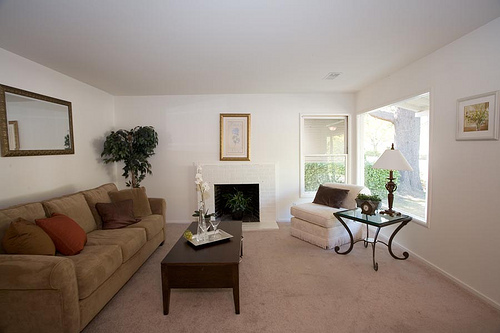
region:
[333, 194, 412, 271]
a glass and wrought iron end table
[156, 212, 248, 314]
a wooden rectangular coffee table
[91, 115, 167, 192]
a fake house tree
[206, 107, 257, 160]
a picture in a gold frame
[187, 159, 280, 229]
a white fire place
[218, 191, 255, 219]
a plant inside the fireplace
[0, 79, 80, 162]
a large bronze mirror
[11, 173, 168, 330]
a soft brown sofa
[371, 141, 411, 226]
an ornate lamp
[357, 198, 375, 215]
a small clock on the table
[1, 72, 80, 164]
Mirror hanging on the wall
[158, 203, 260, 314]
Brown coffee table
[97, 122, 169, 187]
Tall green plant in corner of room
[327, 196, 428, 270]
Glass top table with metal frame and legs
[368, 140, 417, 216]
Table lamp with a white shade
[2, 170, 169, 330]
Light brown sofa with pillows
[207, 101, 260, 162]
Picture on the wall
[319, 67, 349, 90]
Air vent in ceiling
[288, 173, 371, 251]
White armless chair with brown pillow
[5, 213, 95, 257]
Brown and rust colored pillows on a couch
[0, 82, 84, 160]
Gold framed mirror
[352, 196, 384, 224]
A clock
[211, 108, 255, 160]
A gold framed picture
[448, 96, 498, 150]
A silver framed picture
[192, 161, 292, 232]
A fireplace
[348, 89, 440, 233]
A large glass window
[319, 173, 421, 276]
A glass top side table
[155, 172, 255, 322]
A wooden coffee table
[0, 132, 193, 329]
A brown suede couch with throw pillows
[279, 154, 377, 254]
A white chair with throw pillow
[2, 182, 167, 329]
Brown sofa in living room.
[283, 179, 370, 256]
White chair in corner near windows.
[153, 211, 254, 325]
Coffee table in front of sofa.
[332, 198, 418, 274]
Glass end table next to chair and window.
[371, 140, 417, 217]
Lamp with white shade on end table.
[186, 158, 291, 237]
Fireplace on wall across from sofa.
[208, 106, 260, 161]
Picture hanging on wall over fireplace.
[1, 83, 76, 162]
Mirror hanging on wall over sofa.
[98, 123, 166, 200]
Artificial tree in corner next to sofa.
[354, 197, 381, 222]
Clock on end table next to white chair.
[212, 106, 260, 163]
Painting on a white wall in a gold frame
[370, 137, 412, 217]
Dark colored lamp with white shade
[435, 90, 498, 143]
Painting on a white wall with a white frame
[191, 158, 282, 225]
White fireplace on a white wall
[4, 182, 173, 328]
Light brown sofa covered in pillows of various colors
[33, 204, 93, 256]
Reddish pillow sitting on tan sofa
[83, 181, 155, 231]
Two pillows sitting on a sofa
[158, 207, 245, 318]
Dark wooden coffee table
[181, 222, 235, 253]
Metal tray with two wine glasses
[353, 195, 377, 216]
Brown clock with white face